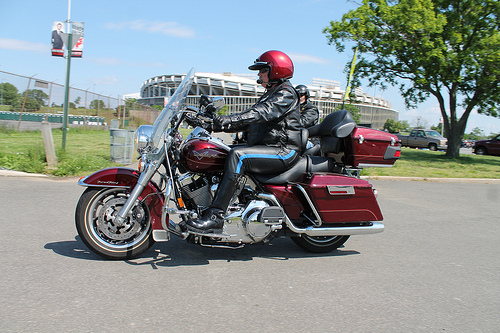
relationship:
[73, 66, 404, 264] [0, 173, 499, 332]
motorcycle on road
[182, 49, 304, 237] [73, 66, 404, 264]
man on a motorcycle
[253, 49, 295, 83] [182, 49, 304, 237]
helmet on rider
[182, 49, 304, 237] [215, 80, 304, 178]
man wearing leather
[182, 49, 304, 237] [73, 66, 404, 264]
man on motorcycle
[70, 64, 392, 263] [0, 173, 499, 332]
motorcycle on road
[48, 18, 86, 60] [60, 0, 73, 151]
sign on a pole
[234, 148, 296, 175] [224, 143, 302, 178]
stripe on pants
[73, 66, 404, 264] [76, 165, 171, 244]
motorcycle has a fender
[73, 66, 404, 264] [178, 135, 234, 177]
motorcycle has a gas tank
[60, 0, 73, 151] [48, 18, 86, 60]
pole has a sign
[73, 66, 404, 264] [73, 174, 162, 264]
motorcycle has a wheel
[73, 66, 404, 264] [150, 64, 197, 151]
motorcycle has a windshield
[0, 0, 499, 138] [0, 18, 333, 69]
sky has a cloud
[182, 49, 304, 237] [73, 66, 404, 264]
man riding a motorcycle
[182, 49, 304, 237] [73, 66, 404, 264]
rider on a motorcycle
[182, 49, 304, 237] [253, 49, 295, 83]
rider has on a helmet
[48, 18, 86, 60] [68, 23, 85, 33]
sign has lettering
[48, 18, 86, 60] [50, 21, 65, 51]
sign and man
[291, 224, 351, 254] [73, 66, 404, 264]
tire on motorcycle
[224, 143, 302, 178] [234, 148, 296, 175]
pants have a stripe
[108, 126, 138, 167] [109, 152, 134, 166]
can for trash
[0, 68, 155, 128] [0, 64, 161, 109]
barbed-wire has barbed-wire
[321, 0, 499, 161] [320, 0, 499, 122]
tree has leaves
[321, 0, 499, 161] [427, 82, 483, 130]
tree has branches